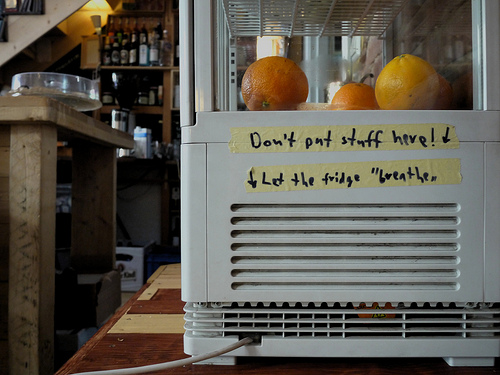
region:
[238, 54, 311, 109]
an orange in a fridge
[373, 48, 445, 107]
lemon in a fridge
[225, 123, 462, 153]
tape on a white fridge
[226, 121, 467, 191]
two strips of tape on a fridge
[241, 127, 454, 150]
black handwritten print on a tape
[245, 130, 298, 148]
handwritten print on a tape reading Don't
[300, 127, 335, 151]
handwritten print reading put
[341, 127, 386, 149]
handwritten print reading stuff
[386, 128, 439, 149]
handwritten print on a tape reading here!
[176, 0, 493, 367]
small white fridge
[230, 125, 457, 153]
black letters on a piece of tape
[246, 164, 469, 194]
black writing on tape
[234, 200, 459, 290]
a vent in the refridgerator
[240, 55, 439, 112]
round delicious oranges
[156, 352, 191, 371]
a gray cord on the refridgerator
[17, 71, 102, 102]
a silver pot on the counter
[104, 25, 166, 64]
several bottles of liquor on shelf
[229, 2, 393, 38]
a white wire shelf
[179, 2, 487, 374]
a small white refridgerator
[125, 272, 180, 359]
a wooden table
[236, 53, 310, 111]
a single dark orange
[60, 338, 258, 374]
a white power cord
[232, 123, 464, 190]
a makeshift duct tape sign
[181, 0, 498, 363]
a see through refridgerator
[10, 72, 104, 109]
a clear plastic tray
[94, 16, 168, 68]
a row of bottles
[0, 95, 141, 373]
a wooden table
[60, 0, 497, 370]
a fridge on a wooden table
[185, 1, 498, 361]
a fridge full of oranges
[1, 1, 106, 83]
the corner of a wooden staircase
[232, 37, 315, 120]
an orange in the refrigerator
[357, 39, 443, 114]
a lemon in the refrigerator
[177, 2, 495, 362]
a silver refrigerator on the table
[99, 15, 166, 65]
a collection of bottles on a shelf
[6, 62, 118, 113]
a dessert tray on table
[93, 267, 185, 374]
a checkered table in a store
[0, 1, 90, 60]
stairs leading upstairs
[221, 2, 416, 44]
a tray in the refrigerator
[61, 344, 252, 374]
a cord coming from the refrigerator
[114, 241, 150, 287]
a white box on the floor